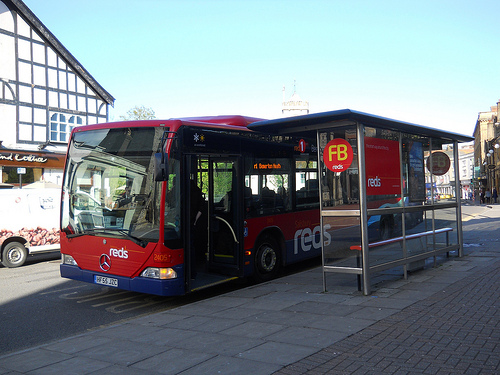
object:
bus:
[58, 111, 427, 301]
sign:
[322, 137, 354, 173]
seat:
[349, 227, 453, 293]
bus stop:
[244, 107, 480, 300]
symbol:
[97, 252, 113, 272]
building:
[0, 0, 117, 188]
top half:
[0, 0, 118, 110]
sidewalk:
[0, 220, 499, 375]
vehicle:
[0, 182, 67, 270]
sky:
[22, 0, 500, 136]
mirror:
[152, 151, 169, 183]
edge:
[354, 123, 370, 294]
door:
[205, 153, 240, 277]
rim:
[6, 244, 26, 266]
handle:
[212, 213, 241, 245]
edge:
[183, 274, 242, 294]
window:
[242, 155, 294, 221]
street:
[0, 198, 500, 360]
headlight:
[136, 266, 178, 281]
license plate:
[92, 274, 119, 287]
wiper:
[117, 229, 148, 249]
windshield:
[60, 125, 181, 242]